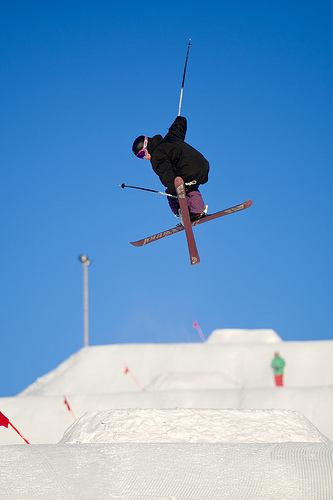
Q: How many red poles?
A: Four.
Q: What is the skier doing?
A: Tricks.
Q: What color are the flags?
A: Red.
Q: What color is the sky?
A: Blue.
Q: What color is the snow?
A: White.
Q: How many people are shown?
A: 2.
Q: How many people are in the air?
A: 1.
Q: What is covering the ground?
A: Snow.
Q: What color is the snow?
A: White.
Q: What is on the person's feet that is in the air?
A: Skis.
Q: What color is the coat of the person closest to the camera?
A: Black.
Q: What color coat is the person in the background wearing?
A: Green.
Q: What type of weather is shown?
A: Clear and cold.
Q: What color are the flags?
A: Red.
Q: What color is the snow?
A: White.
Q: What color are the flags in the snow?
A: Orange.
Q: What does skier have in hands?
A: Ski poles.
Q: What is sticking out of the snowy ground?
A: Flags.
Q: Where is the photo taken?
A: Ski slopes.